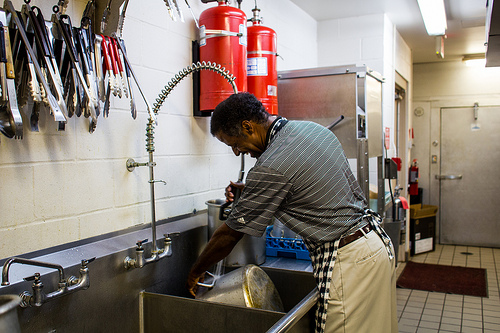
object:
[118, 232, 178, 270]
faucet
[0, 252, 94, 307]
faucet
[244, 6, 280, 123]
fire extinguisher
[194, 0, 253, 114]
fire extinguisher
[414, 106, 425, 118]
clock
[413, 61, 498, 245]
wall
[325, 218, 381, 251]
belt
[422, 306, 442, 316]
tile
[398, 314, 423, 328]
tile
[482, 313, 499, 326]
tile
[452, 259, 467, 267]
tile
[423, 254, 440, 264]
tile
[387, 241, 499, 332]
floor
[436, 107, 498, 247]
door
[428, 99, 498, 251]
cooler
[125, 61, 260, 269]
faucet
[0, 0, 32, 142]
cooking tools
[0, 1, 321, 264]
wall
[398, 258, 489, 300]
rug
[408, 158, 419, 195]
fire extinguisher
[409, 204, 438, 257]
box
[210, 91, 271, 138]
hair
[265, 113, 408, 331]
apron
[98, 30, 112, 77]
handles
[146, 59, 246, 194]
coil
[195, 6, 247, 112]
tanks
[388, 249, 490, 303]
mat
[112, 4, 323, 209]
wall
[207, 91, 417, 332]
man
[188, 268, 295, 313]
pot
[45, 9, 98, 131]
utensils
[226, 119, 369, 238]
shirt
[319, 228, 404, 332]
pants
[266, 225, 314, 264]
dish rack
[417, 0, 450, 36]
light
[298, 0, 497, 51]
ceiling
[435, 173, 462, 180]
handle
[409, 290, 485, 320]
tiles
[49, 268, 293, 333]
basins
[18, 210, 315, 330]
sink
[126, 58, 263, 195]
tap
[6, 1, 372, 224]
wall